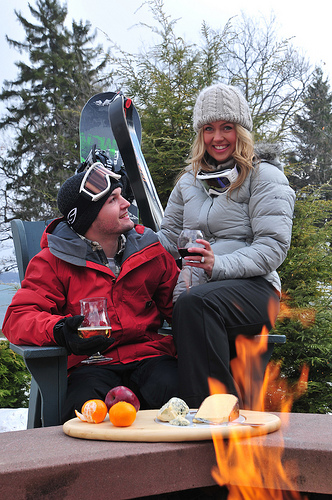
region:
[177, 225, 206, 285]
A glass of red wine held by this woman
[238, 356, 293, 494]
A bon fire next to this couple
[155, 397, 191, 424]
A chunk of blue cheese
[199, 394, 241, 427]
A chunk of brie cheese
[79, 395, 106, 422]
A half-peeled orange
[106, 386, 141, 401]
A large red apple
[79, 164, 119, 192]
A pair of ski glasses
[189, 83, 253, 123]
A light gray wool hat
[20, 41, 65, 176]
A tall pine tree in the rear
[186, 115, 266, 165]
A smile face of a blond lady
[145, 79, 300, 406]
a beautiful young lady.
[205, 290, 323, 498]
a fire near a cutting board.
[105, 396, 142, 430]
an orange on a cutting board.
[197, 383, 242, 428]
a piece of a food.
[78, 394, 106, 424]
an orange on a cutting board.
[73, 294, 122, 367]
a glass in a man's hand.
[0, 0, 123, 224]
a green pine tree.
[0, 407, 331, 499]
a bar with food on it.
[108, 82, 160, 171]
the top of a snowboard.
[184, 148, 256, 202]
a pair of snow goggles.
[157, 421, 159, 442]
THE CHOPPIG BOARD IS WOODEN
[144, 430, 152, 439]
THE CHOPPIG BOARD IS WOODEN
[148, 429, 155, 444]
THE CHOPPIG BOARD IS WOODEN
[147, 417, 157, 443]
THE CHOPPIG BOARD IS WOODEN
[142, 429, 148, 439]
THE CHOPPIG BOARD IS WOODEN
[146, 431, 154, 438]
THE CHOPPIG BOARD IS WOODEN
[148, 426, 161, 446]
THE CHOPPIG BOARD IS WOODEN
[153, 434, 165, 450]
THE CHOPPIG BOARD IS WOODEN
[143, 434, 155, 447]
THE CHOPPIG BOARD IS WOODEN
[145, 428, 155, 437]
THE CHOPPIG BOARD IS WOODEN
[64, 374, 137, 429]
fruit on the plate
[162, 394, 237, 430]
cheese on the board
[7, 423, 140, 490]
rim of a fire pit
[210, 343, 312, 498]
fire in the fire pit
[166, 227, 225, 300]
woman holding wine glass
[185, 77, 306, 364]
woman sitting on arm of chair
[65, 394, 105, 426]
orange is missing peel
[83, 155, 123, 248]
ski goggles on his head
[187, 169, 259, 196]
goggles are white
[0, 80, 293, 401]
man and woman sitting on a chair together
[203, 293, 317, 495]
fire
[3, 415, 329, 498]
cement border around fire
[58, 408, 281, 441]
large wooden platter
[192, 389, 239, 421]
wedge of cheese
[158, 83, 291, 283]
woman wearing a grey coat and hat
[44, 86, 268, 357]
man and woman both holding drinking glasses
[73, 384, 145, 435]
fruit on platter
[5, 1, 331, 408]
trees behind man and woman